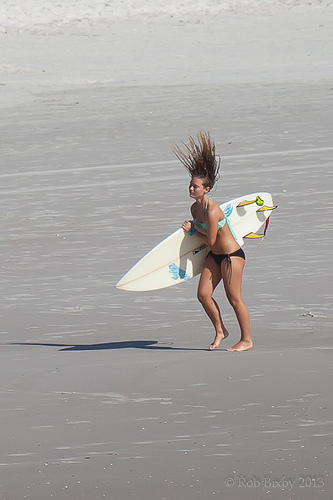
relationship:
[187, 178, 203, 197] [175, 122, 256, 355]
face on woman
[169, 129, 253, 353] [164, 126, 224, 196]
girl flipping hair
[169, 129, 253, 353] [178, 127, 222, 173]
girl in hair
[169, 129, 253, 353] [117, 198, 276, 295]
girl holding surfboard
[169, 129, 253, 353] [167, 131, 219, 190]
girl with hair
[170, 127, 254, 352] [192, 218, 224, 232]
woman wearing bikini top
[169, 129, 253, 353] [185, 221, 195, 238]
girl wearing wristband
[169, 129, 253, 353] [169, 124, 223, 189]
girl with hair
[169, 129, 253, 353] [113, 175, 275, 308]
girl holding surfboard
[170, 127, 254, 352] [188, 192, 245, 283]
woman wearing swim suit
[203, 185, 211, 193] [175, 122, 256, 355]
ear of woman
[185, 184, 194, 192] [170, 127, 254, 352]
nose of woman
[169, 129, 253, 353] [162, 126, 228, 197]
girl flipping hair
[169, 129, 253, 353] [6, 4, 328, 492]
girl on sand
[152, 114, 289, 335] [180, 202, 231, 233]
girl with top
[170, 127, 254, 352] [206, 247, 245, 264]
woman wearing bikini bottoms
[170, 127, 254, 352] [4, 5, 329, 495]
woman standing on beach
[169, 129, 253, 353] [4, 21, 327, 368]
girl standing on sand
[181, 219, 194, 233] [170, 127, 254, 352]
hand walking woman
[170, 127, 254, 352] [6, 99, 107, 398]
woman at beach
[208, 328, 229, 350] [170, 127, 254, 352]
foot of woman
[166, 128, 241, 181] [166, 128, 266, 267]
hair of woman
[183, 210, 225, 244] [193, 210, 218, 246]
arm of arm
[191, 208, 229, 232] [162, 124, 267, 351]
bikini top of woman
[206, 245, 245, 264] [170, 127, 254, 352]
bikini bottoms of woman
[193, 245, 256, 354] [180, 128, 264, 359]
legs of woman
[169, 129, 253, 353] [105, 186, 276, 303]
girl holding surfboard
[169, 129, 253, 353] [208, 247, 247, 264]
girl with black bottoms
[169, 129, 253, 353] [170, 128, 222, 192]
girl standing hair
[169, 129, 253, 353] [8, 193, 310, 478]
girl walking beach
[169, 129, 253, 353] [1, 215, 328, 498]
girl walking sand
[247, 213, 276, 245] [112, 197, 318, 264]
strap on surfboard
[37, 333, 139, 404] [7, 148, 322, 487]
sand on beach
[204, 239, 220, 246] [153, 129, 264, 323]
elbow walking woman